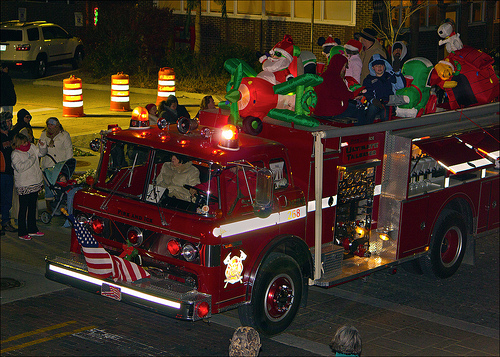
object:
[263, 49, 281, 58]
sunglasses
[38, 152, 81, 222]
stroller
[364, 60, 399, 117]
toys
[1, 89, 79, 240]
street corner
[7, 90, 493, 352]
street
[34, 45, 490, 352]
fire truck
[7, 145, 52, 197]
coat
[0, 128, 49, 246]
woman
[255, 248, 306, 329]
tire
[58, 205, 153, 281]
american flag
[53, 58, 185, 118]
construction barrel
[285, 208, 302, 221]
numbers on white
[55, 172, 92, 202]
baby in stroller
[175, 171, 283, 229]
driver side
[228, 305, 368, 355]
heads of two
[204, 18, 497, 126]
engine carrying toys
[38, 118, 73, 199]
people watching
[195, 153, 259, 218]
person driving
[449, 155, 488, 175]
stripe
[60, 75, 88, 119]
cones on fire truck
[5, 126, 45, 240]
people standing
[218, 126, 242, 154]
lights on top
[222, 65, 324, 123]
christmas balloons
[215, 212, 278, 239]
white stripe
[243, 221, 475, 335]
two tires visible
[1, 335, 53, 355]
yellow lines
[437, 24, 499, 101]
christmas decoration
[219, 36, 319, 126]
plush santa figure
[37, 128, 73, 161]
wearing white coat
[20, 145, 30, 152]
red scarf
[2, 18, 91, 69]
utility vehicle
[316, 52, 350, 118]
hooded sweatshirt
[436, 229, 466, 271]
red hub cabs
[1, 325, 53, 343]
yellow stripes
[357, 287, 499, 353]
part of a road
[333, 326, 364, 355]
part of a hair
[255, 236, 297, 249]
part of a rim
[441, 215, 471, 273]
part of a wheel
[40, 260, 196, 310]
edge of a lorry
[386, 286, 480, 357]
road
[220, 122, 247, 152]
part of a lamp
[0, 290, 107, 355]
of a road